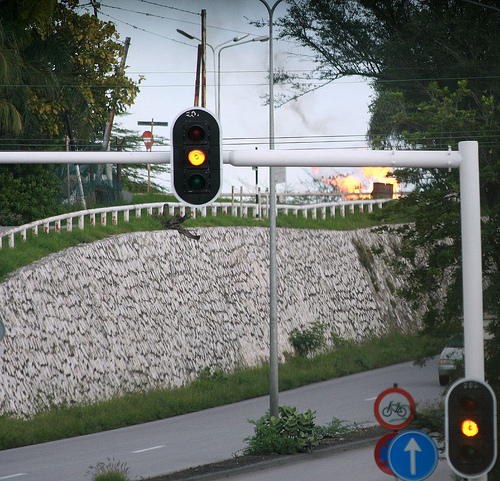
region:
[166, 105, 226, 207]
The stop light is black.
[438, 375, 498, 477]
The stop light is black.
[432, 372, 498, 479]
The stop light is shining yellow.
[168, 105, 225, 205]
The stop light is shining yellow.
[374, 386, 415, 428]
The sign is red, white and black.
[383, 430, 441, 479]
The sign is blue and white.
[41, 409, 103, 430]
The grass is green.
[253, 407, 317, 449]
The leaves by the pole are green.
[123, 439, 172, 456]
There is a white stripe on the road.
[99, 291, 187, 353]
The wall is made of rock.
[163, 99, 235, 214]
street light on yellow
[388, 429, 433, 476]
blue sign with white arrow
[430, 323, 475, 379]
car driving down the street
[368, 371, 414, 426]
cirle sign with bicycle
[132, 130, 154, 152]
red stop sign on wood pole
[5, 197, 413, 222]
white fence by road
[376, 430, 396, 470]
red and blue circle sign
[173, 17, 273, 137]
street lights on pole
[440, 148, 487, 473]
traffic light on white pole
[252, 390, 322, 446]
small bush around pole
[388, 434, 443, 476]
the blue round arrow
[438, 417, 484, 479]
the yellow stop light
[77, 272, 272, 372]
the grey stone wall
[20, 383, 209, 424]
the green grass on the road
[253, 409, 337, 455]
the green flowers around the pole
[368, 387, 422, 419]
the bike sign in red and white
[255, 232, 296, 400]
the tall grey pole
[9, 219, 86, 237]
the white short fence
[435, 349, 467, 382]
the front of the grey car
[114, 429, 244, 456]
the white lines in road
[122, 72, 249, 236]
Yellow lit traffic light.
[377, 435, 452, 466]
Blue circular direction sign.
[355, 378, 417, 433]
Red and white sign with a bike on it.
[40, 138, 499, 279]
White traffic light pole.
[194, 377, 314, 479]
weeds at base of gray pole.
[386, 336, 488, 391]
Car driving down road.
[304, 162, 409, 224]
Flames in the distance.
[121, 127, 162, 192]
Red stop sign on top of image.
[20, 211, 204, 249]
White guard rail along road.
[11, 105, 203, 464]
Road is above another road.